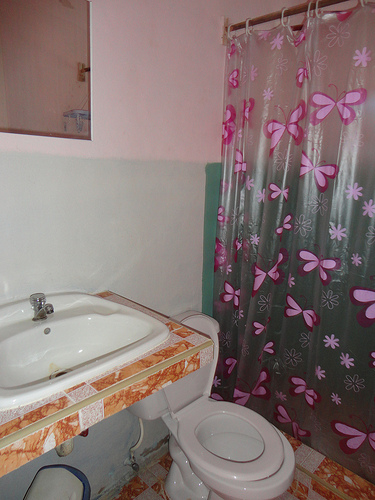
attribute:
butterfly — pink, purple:
[284, 380, 331, 413]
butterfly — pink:
[310, 83, 366, 137]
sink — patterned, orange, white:
[1, 290, 172, 412]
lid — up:
[159, 315, 225, 407]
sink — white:
[2, 308, 162, 406]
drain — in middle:
[50, 366, 71, 377]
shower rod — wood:
[226, 1, 349, 32]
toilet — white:
[118, 303, 301, 498]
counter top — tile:
[1, 292, 207, 477]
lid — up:
[160, 318, 218, 411]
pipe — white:
[127, 418, 143, 461]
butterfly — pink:
[296, 247, 344, 286]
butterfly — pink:
[297, 149, 339, 190]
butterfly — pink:
[307, 85, 367, 126]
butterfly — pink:
[262, 100, 307, 156]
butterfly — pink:
[283, 294, 318, 328]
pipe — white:
[54, 429, 80, 467]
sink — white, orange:
[16, 283, 162, 415]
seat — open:
[152, 408, 292, 477]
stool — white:
[163, 392, 294, 498]